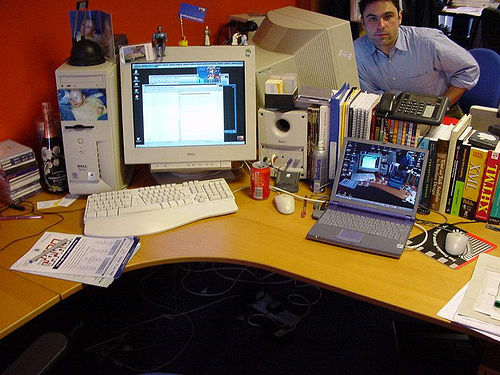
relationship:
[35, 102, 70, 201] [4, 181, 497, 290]
bottle on desk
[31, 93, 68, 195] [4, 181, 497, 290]
wine on desk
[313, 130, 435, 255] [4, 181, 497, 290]
laptop on desk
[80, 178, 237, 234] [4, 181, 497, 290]
keyboard on desk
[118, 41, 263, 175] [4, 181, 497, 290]
monitor on desk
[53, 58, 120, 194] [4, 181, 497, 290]
tower on desk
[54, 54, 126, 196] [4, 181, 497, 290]
cpu on desk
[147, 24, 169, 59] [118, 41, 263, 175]
toy on monitor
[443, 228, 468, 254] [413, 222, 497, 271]
mouse on mousepad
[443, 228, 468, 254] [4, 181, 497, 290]
mouse on desk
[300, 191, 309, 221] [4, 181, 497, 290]
pen on desk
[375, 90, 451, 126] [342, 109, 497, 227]
phone on books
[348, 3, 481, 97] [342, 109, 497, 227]
man behind books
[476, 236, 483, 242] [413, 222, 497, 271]
red black mousepad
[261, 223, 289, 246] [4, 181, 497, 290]
brown wooden desk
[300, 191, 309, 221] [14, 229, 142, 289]
pen on paper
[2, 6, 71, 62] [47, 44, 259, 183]
wall behind computer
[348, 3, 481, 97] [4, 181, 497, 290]
man at desk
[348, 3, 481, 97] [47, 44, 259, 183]
man at computer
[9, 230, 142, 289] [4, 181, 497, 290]
papers on desk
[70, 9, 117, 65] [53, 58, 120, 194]
picture on tower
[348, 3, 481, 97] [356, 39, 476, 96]
man wearing shirt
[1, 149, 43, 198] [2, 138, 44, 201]
stack of cds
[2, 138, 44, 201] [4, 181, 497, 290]
cds on desk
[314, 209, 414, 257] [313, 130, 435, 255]
small silver laptop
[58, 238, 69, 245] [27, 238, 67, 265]
grey blue pen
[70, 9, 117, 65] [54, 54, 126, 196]
picture on cpu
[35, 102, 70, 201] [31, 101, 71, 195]
bottle of champagne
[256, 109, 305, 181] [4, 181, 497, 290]
sub-woofer on desk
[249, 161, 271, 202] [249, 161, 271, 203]
can of cola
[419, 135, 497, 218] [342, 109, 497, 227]
row of books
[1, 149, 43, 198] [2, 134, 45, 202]
stack of discs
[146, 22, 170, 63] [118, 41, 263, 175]
figurine on monitor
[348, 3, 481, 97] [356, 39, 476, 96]
man in shirt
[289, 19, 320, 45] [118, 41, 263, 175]
white big monitor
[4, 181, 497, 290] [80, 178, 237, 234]
desk top keyboard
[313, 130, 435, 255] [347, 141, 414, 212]
laptop on screen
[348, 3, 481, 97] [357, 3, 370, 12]
man with hair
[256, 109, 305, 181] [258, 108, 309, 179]
sub-woofer for sub-woofer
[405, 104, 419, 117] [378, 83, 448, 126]
black corded phone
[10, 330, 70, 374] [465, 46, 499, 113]
armrest on chair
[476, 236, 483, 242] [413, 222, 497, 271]
red white mousepad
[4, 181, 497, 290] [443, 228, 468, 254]
desk top mouse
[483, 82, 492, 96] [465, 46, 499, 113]
blue on chair